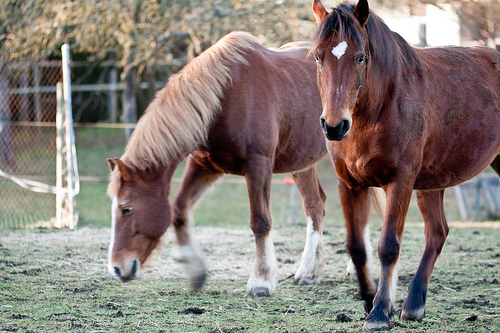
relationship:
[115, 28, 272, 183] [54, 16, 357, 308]
mane on horse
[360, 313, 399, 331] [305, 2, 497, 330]
hoof on horse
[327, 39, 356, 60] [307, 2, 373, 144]
spot on face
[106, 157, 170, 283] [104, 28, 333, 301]
head of horse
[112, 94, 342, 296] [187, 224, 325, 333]
horse has four hooves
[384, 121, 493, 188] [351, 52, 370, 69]
horse has dark eyes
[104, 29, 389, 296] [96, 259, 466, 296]
horse on grass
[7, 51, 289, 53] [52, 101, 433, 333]
trees behind horses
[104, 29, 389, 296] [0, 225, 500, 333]
horse horse eating grass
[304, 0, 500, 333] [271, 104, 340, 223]
horse horse looking at camera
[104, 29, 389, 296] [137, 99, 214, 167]
horse horse has blonde mane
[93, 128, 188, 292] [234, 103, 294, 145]
head of horse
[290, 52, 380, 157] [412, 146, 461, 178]
head of horse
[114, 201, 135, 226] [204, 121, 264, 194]
eye of horse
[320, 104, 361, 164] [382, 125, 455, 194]
nostrils of horse